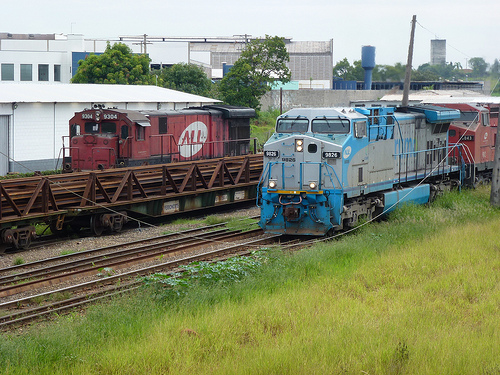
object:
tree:
[468, 56, 489, 74]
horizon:
[341, 50, 489, 74]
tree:
[332, 57, 354, 82]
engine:
[69, 105, 261, 169]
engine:
[258, 103, 463, 239]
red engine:
[440, 95, 500, 174]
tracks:
[1, 248, 261, 327]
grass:
[287, 241, 327, 273]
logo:
[178, 119, 209, 158]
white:
[201, 124, 206, 140]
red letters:
[181, 130, 191, 145]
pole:
[401, 16, 419, 104]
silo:
[431, 39, 446, 69]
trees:
[204, 33, 292, 109]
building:
[0, 84, 220, 175]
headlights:
[293, 138, 305, 155]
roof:
[0, 79, 224, 103]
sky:
[3, 2, 499, 37]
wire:
[1, 99, 491, 250]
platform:
[1, 154, 268, 232]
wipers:
[323, 115, 331, 127]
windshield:
[312, 119, 350, 134]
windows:
[38, 64, 50, 81]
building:
[0, 39, 77, 86]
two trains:
[66, 110, 452, 238]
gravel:
[29, 235, 125, 257]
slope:
[303, 193, 499, 285]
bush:
[152, 269, 192, 293]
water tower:
[360, 46, 377, 90]